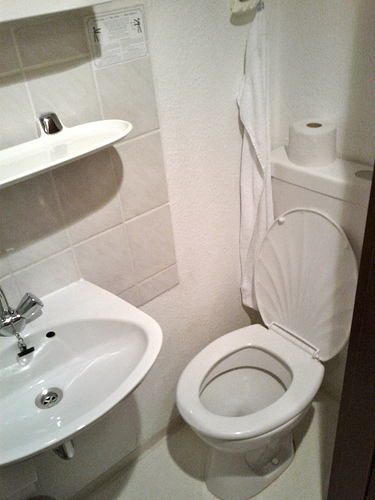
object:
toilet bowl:
[175, 323, 326, 499]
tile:
[124, 201, 176, 286]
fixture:
[39, 112, 62, 135]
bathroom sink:
[0, 299, 163, 465]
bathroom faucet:
[0, 291, 44, 337]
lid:
[252, 208, 359, 361]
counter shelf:
[0, 118, 132, 189]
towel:
[234, 9, 273, 314]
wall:
[179, 53, 240, 288]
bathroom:
[0, 0, 375, 500]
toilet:
[175, 205, 360, 499]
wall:
[0, 203, 9, 259]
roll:
[289, 119, 337, 167]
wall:
[175, 21, 232, 65]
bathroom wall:
[8, 187, 165, 278]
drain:
[35, 387, 63, 408]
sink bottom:
[13, 354, 91, 415]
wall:
[160, 242, 199, 330]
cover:
[287, 121, 336, 170]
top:
[271, 151, 369, 191]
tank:
[267, 144, 374, 269]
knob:
[0, 286, 27, 338]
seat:
[176, 324, 325, 441]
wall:
[0, 13, 97, 132]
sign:
[84, 3, 150, 69]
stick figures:
[87, 9, 133, 90]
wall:
[87, 0, 140, 77]